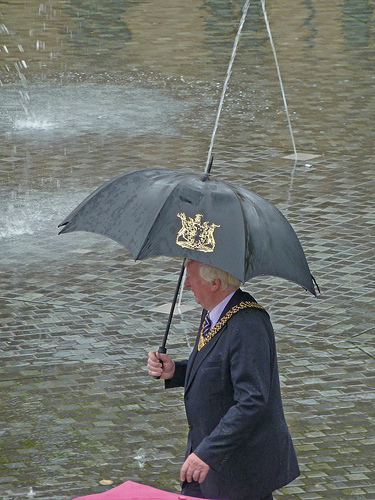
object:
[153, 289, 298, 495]
coat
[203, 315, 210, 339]
tie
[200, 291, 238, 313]
neck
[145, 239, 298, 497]
man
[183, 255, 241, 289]
hair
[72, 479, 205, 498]
object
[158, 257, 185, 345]
umbrella stick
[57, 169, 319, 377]
umbrella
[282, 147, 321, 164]
tile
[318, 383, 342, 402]
tile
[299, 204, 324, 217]
tile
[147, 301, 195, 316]
tile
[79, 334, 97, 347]
tile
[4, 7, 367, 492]
ground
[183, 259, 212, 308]
profile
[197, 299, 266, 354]
chain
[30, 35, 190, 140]
wet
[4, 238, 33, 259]
brick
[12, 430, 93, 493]
brick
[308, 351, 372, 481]
brick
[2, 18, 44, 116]
rail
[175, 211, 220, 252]
symbol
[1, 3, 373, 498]
walkway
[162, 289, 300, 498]
suit jacket